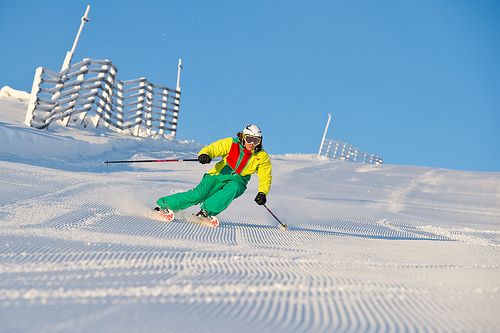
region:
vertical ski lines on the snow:
[184, 236, 347, 326]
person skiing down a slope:
[94, 92, 316, 239]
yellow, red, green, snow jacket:
[197, 119, 277, 198]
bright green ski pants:
[157, 163, 250, 216]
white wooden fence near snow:
[27, 46, 192, 149]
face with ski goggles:
[242, 128, 265, 153]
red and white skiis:
[148, 199, 226, 235]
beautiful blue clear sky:
[259, 12, 458, 113]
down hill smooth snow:
[334, 167, 453, 272]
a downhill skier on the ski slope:
[152, 122, 269, 223]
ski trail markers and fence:
[20, 0, 180, 140]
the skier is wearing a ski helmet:
[242, 122, 262, 138]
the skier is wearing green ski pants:
[157, 171, 249, 217]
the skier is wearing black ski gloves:
[255, 191, 266, 204]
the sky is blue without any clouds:
[181, 1, 498, 125]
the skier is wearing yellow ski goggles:
[242, 133, 262, 147]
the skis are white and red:
[151, 205, 176, 221]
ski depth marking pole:
[316, 110, 333, 160]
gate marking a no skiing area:
[24, 4, 184, 142]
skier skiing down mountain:
[168, 122, 282, 233]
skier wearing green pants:
[192, 171, 246, 213]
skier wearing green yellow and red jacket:
[216, 143, 267, 174]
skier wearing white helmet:
[235, 117, 260, 136]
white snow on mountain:
[15, 141, 104, 323]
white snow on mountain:
[109, 230, 466, 324]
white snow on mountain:
[302, 169, 470, 242]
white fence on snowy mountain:
[9, 46, 184, 150]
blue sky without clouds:
[109, 5, 484, 60]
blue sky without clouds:
[372, 22, 479, 159]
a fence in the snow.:
[24, 50, 206, 162]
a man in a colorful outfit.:
[146, 121, 292, 242]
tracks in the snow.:
[261, 251, 390, 327]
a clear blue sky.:
[4, 0, 496, 175]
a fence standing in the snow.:
[309, 99, 399, 161]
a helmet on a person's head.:
[229, 105, 275, 153]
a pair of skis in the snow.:
[138, 204, 238, 232]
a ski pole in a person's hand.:
[255, 196, 309, 244]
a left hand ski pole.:
[97, 134, 232, 187]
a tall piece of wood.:
[160, 49, 191, 142]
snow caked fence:
[26, 52, 190, 141]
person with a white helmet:
[236, 117, 266, 158]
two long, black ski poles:
[98, 155, 298, 237]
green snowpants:
[156, 166, 248, 216]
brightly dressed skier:
[96, 111, 306, 253]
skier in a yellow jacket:
[193, 113, 290, 193]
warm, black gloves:
[193, 152, 266, 208]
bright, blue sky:
[279, 28, 476, 110]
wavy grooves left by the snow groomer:
[51, 242, 339, 322]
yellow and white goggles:
[241, 134, 264, 145]